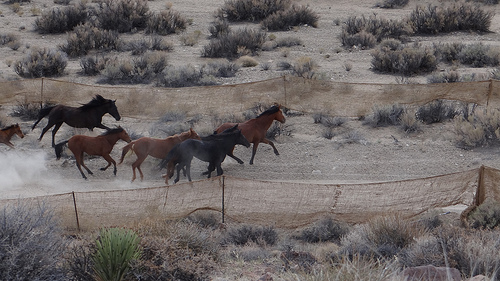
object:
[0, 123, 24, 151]
horse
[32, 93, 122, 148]
horse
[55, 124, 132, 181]
horse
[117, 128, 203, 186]
horse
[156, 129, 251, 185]
horse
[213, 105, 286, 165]
horse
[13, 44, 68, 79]
bush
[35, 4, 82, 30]
bush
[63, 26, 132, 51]
bush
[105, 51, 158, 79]
bush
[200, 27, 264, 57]
bush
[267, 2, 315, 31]
bush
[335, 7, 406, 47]
bush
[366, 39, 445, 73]
bush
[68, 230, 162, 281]
bush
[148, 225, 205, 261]
bush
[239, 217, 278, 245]
bush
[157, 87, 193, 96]
net